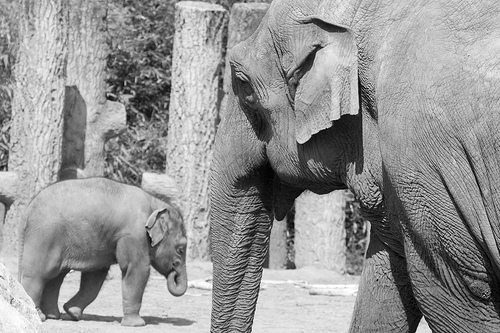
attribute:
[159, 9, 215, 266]
tree — large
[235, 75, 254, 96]
eye — open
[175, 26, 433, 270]
elephant — wrinkly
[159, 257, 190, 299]
trunk — curled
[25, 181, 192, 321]
elephant — small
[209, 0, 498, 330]
elephant — walking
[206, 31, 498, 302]
elephant — adult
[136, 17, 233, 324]
tree — gray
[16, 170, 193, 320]
elephant — small, gray, baby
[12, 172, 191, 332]
baby elephant — lighter colored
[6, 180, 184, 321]
elephants — small, big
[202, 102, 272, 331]
elephant's trunk — hanging, adult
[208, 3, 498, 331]
mother elephant — dark colored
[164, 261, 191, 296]
baby trunk — curled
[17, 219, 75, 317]
legs — back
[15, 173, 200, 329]
elephant — walking